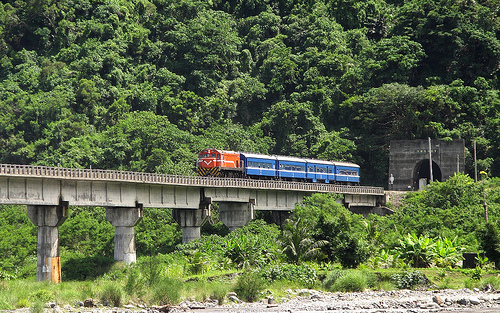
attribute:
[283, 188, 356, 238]
tree — green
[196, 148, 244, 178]
engine — red, orange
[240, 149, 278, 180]
train car — blue, white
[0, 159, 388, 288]
bridge — grey, for railroad tracks, stone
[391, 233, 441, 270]
bush — green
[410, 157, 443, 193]
archway — dark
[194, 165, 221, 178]
bumper — black, yellow